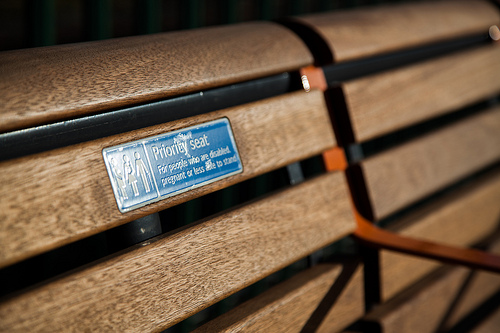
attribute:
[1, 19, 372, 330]
bench — wooden, brown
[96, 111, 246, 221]
sign — blue, white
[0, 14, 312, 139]
backplate — woode, brown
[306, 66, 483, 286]
handrail — brown, wooden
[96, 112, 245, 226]
signboard — blue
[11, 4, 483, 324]
seats — priority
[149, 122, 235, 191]
letters — white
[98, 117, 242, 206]
sign — blue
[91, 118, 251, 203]
sign — blue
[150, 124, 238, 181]
letters — white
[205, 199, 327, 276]
bench slat — wooden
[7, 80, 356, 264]
bench slat — wooden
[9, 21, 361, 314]
bench — wooden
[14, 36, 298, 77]
bench slat — wooden, curved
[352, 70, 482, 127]
bench slat — blurred, wooden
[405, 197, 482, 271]
bench slat — wooden, another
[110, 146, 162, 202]
logo — people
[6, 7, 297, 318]
background — black